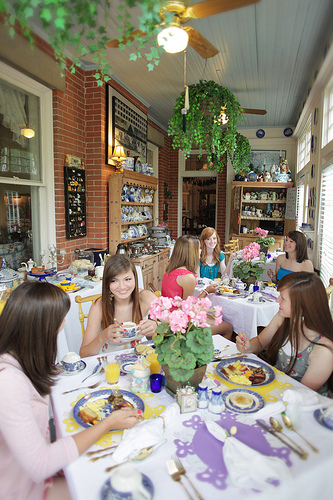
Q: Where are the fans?
A: Ceiling.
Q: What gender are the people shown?
A: Female.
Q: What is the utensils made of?
A: Metal.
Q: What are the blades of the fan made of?
A: Wood.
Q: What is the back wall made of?
A: Brick.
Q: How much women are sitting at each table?
A: Three.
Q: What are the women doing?
A: Eating.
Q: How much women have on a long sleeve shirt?
A: One.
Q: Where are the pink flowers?
A: On the table.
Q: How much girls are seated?
A: Six.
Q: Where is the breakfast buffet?
A: Behind the girls.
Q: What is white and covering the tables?
A: The tablecloth.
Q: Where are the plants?
A: Hanging above.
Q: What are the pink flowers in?
A: A square pot.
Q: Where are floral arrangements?
A: In the center of the tables.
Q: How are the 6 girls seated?
A: 3 at a table.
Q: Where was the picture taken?
A: At a restaurant.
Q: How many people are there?
A: Six.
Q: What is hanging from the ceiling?
A: A plant.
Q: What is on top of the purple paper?
A: A Napkin.